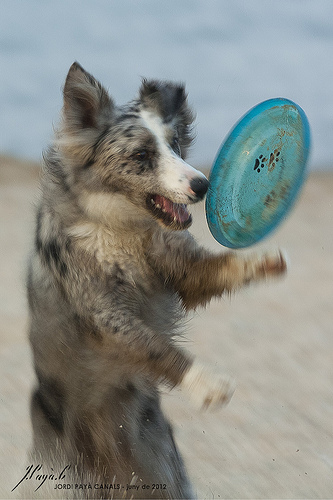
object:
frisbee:
[205, 97, 313, 250]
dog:
[26, 58, 290, 500]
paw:
[201, 245, 297, 290]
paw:
[179, 352, 238, 414]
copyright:
[12, 464, 167, 491]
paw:
[269, 149, 281, 167]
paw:
[253, 154, 266, 174]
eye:
[171, 135, 183, 158]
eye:
[128, 148, 155, 165]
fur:
[52, 205, 141, 402]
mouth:
[142, 186, 199, 227]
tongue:
[155, 193, 188, 222]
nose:
[149, 148, 212, 198]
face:
[105, 117, 209, 228]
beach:
[1, 145, 333, 499]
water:
[2, 1, 332, 179]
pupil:
[137, 151, 142, 157]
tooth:
[172, 214, 178, 221]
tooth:
[162, 206, 167, 214]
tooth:
[156, 203, 161, 211]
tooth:
[149, 197, 154, 205]